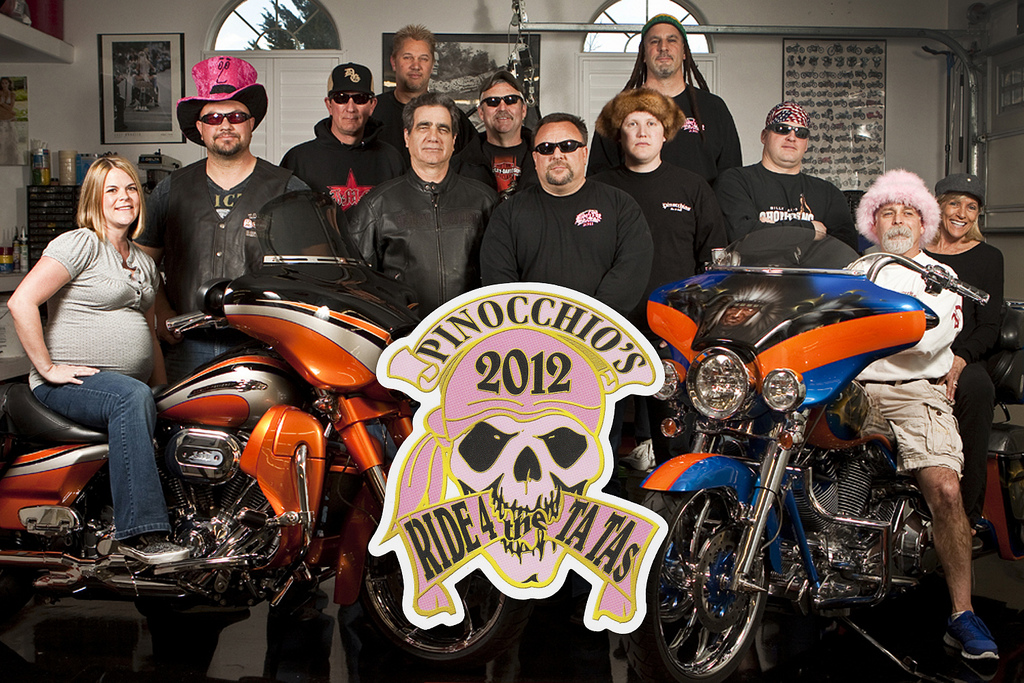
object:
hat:
[176, 55, 268, 147]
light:
[685, 346, 760, 421]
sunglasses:
[532, 140, 586, 155]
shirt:
[28, 227, 161, 392]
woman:
[922, 173, 1005, 538]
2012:
[474, 347, 573, 396]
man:
[480, 112, 654, 321]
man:
[716, 102, 861, 269]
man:
[132, 55, 333, 384]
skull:
[366, 281, 668, 636]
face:
[533, 113, 588, 193]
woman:
[5, 157, 190, 565]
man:
[843, 167, 999, 660]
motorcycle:
[619, 227, 1024, 683]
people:
[5, 13, 1005, 660]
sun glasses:
[765, 123, 811, 139]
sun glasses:
[198, 112, 253, 125]